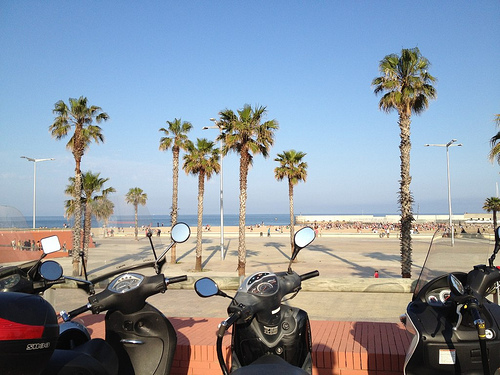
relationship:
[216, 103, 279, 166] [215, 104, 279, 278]
fronds on palm tree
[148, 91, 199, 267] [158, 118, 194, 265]
leaves on palm tree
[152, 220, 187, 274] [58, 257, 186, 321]
mirror on handlebars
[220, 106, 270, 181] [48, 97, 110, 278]
fronds on palm tree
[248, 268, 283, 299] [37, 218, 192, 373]
gauge on scooter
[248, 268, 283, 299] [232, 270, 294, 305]
gauge on dashboard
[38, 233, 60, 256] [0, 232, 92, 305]
mirror on scooter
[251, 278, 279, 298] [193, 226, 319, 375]
speedometer on motorbike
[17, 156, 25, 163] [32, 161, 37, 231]
light on post